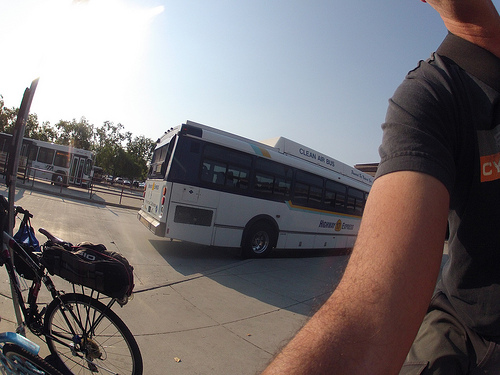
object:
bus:
[138, 121, 357, 258]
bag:
[42, 237, 136, 300]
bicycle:
[1, 196, 143, 374]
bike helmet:
[13, 209, 40, 280]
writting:
[296, 144, 337, 168]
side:
[281, 137, 341, 175]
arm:
[268, 140, 450, 375]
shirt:
[375, 31, 499, 375]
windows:
[200, 152, 230, 190]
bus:
[0, 131, 96, 187]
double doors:
[68, 153, 88, 185]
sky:
[1, 0, 384, 119]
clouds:
[4, 1, 175, 123]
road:
[0, 200, 143, 238]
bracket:
[41, 276, 122, 344]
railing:
[21, 167, 140, 201]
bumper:
[136, 210, 164, 236]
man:
[259, 1, 499, 374]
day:
[0, 1, 498, 374]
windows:
[226, 154, 247, 189]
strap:
[435, 34, 499, 90]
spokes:
[66, 300, 98, 335]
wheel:
[242, 217, 276, 260]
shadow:
[158, 246, 314, 314]